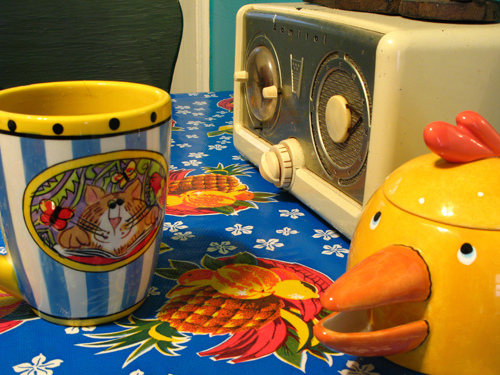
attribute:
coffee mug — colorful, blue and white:
[3, 80, 163, 322]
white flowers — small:
[220, 218, 296, 252]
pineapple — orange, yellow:
[171, 267, 306, 349]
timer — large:
[223, 4, 438, 231]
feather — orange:
[421, 109, 498, 166]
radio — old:
[235, 4, 499, 225]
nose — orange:
[308, 240, 433, 359]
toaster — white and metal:
[238, 30, 445, 285]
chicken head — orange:
[310, 107, 499, 369]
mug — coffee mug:
[6, 74, 176, 331]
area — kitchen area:
[2, 7, 482, 367]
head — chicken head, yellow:
[325, 113, 481, 363]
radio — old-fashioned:
[228, 3, 484, 241]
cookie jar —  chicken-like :
[321, 110, 481, 361]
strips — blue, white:
[3, 138, 71, 162]